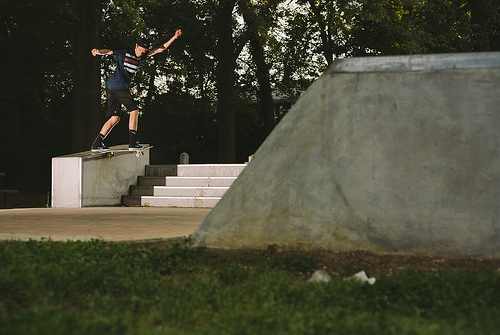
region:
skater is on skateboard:
[89, 30, 180, 151]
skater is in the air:
[92, 30, 183, 157]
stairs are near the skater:
[130, 159, 234, 205]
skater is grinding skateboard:
[90, 145, 149, 159]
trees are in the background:
[40, 15, 304, 127]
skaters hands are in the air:
[92, 29, 184, 55]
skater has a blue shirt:
[107, 47, 137, 85]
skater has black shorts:
[105, 85, 137, 117]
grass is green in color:
[71, 255, 293, 329]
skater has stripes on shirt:
[120, 53, 139, 73]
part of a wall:
[349, 170, 371, 189]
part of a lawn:
[314, 300, 324, 312]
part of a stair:
[181, 170, 192, 175]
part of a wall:
[102, 182, 109, 192]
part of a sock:
[133, 140, 140, 151]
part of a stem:
[221, 104, 243, 128]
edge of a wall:
[286, 111, 299, 134]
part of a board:
[116, 146, 119, 153]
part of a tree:
[217, 74, 254, 113]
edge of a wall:
[71, 163, 83, 185]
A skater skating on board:
[85, 27, 186, 157]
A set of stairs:
[120, 157, 247, 207]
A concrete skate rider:
[190, 60, 495, 250]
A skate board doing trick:
[92, 144, 151, 158]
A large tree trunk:
[204, 2, 240, 159]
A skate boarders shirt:
[112, 47, 142, 90]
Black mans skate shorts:
[102, 77, 134, 121]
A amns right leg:
[127, 108, 145, 151]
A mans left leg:
[82, 115, 122, 153]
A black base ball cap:
[136, 35, 151, 53]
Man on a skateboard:
[69, 4, 197, 168]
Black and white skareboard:
[85, 141, 208, 166]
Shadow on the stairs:
[93, 180, 218, 212]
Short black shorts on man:
[82, 77, 166, 119]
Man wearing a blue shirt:
[96, 27, 169, 118]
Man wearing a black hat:
[114, 29, 166, 59]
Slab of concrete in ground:
[304, 29, 499, 253]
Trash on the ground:
[294, 246, 389, 316]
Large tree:
[208, 3, 263, 138]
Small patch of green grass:
[90, 274, 115, 296]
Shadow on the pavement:
[122, 149, 174, 224]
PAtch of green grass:
[5, 241, 45, 283]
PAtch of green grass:
[58, 239, 101, 279]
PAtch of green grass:
[103, 239, 154, 282]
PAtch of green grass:
[160, 249, 210, 294]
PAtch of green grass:
[220, 266, 292, 323]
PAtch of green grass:
[304, 282, 369, 334]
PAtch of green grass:
[388, 269, 437, 316]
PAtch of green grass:
[445, 266, 499, 325]